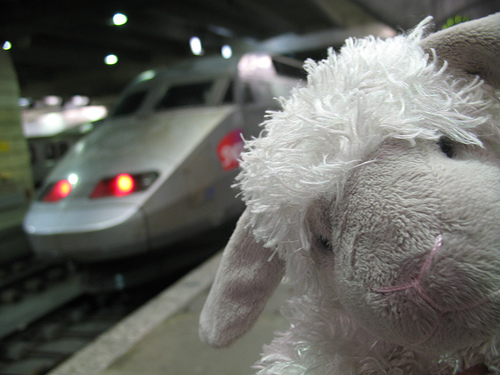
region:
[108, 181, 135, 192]
headlight of a train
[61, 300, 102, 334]
section of a railway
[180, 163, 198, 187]
part of a body of a train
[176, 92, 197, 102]
windscreen of a train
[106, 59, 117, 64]
white light in the background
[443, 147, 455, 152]
eye of a teddybear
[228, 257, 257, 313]
section of a teddybear's ear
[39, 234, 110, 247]
fron section of a train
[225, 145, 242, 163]
red mark on a train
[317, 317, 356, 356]
section of a teddybear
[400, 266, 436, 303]
nose of a doll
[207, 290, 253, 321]
ear of a doll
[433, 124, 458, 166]
left eye of a doll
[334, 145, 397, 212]
head of a doll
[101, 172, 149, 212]
part of an indicator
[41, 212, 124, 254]
front of a train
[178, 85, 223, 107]
part of a window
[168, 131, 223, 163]
edge of the train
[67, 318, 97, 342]
part of a rail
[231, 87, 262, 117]
side of the train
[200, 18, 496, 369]
the toy is facing the camera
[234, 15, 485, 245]
the toy has long strands for hair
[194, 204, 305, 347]
the toy has long ears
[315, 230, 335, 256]
the toy has dark eyes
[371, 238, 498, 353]
a pink configuration in on the toy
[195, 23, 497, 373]
the toys head is at an angle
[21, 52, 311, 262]
a train is in the background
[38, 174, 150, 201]
the lights are turned on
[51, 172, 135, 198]
the lights are red in color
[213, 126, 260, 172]
the train has a logo on the side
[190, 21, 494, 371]
white stuffed lamb facing camera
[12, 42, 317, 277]
silver train on train tracks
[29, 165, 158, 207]
red headlights of train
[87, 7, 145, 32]
lights on in train station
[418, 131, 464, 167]
left eye of stuffed lamb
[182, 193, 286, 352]
right ear of stuffed lamb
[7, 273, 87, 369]
train tracks on the ground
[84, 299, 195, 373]
platform at the train station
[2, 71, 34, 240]
brick column in the background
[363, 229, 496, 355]
pink threaded nose and mouth of lamb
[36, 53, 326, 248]
train is steel and grey